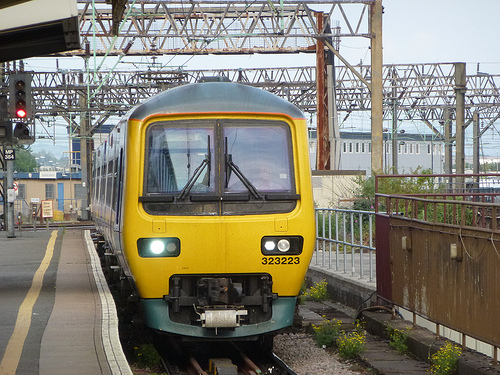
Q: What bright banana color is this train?
A: Yellow.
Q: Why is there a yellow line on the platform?
A: No walking past it.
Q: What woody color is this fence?
A: Brown.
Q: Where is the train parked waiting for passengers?
A: Station.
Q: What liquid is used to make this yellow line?
A: Paint.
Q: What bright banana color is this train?
A: Yellow.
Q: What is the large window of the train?
A: Windshield.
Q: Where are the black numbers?
A: Front of train.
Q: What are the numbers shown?
A: 323223.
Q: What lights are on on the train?
A: Headlights.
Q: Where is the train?
A: Train station.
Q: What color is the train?
A: Yellow.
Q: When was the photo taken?
A: Day time.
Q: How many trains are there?
A: One.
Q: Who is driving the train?
A: The conductor.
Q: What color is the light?
A: Red.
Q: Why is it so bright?
A: Sunny.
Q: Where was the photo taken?
A: Train station.